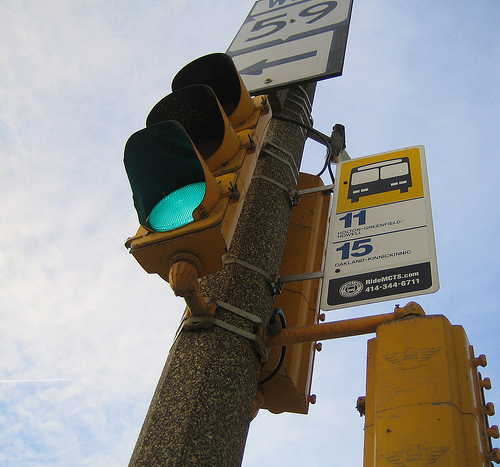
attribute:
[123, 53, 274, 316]
traffic light — for traffic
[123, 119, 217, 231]
covers —  three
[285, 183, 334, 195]
bar —  two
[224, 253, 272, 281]
bracket —  metal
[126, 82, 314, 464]
pole — for street light 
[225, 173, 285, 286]
straps —  metal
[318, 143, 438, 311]
sign —  about bus lines,  bus'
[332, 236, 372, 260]
15 —  bus line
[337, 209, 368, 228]
11 —  bus line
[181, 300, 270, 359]
bands —  metal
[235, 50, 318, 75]
arrow —  black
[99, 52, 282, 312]
traffic light — green, for traffic, yellow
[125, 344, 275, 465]
pole —  metal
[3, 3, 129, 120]
sky — cloudy, blue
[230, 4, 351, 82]
sign — black, white,  vertical,  another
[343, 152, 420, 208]
bus icon —  bus'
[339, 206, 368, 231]
number — blue,  of phone,  for bus line information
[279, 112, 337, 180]
cord — black